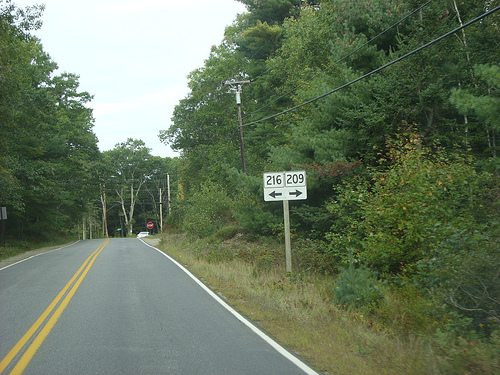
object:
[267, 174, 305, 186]
numbers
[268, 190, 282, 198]
arrow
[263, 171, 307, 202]
sign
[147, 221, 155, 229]
sign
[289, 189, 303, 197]
arrow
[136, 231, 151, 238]
car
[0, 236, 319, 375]
lines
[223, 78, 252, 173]
pole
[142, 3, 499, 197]
wires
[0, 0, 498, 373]
trees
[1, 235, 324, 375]
road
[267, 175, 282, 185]
216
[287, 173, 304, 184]
209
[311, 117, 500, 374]
bushes